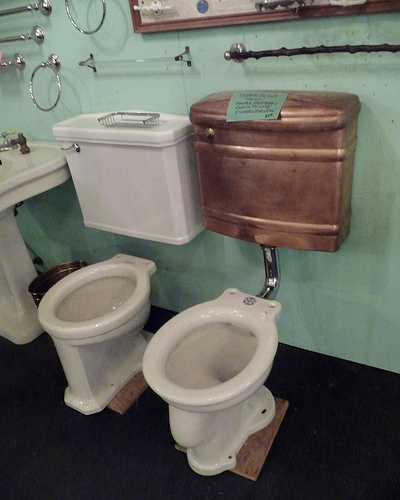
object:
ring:
[29, 53, 62, 111]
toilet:
[37, 111, 206, 416]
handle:
[10, 132, 30, 154]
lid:
[142, 287, 282, 406]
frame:
[255, 244, 278, 300]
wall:
[0, 0, 400, 375]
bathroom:
[0, 0, 400, 500]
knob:
[0, 127, 16, 137]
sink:
[0, 142, 71, 346]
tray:
[97, 111, 160, 129]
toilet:
[141, 90, 360, 475]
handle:
[187, 128, 215, 140]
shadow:
[142, 286, 281, 476]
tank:
[52, 110, 205, 246]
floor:
[0, 303, 400, 500]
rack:
[223, 41, 400, 63]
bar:
[78, 46, 191, 73]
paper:
[225, 90, 288, 123]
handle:
[60, 144, 80, 153]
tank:
[37, 253, 157, 415]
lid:
[52, 112, 192, 147]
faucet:
[0, 130, 19, 151]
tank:
[189, 89, 360, 252]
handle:
[224, 42, 246, 63]